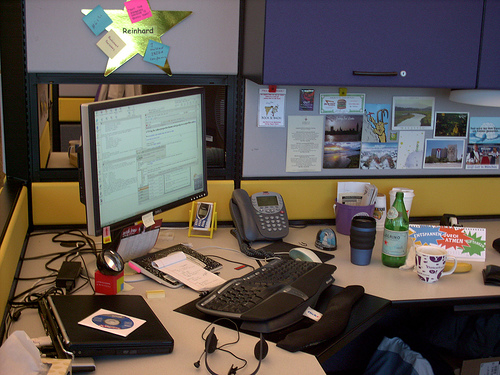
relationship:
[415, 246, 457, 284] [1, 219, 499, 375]
cup on top of desk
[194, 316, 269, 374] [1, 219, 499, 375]
headpiece on top of desk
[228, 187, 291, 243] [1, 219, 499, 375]
telephone on top of desk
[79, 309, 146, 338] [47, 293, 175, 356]
cd on top of laptop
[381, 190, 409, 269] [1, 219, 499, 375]
bottle on top of desk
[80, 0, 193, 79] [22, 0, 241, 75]
star on front of door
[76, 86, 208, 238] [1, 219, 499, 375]
monitor sitting on desk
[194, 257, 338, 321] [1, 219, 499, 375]
keyboard sitting on desk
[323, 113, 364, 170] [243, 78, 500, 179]
picture pasted to wall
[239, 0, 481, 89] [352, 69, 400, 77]
cabinet with handle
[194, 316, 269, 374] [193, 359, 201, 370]
headpiece has microphone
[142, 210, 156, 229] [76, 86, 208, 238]
post it note on front of monitor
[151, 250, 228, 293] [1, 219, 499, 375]
notebook on top of desk